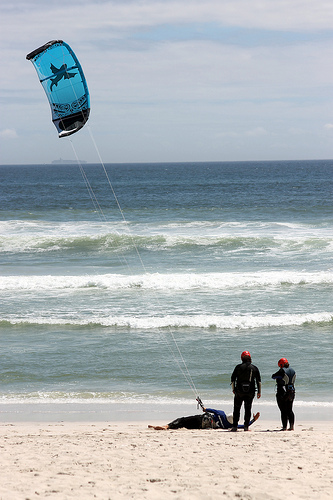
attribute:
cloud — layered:
[0, 1, 331, 48]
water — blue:
[1, 159, 331, 402]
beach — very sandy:
[0, 404, 332, 498]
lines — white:
[66, 126, 170, 306]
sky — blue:
[122, 30, 275, 129]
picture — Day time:
[35, 132, 223, 479]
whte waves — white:
[155, 213, 265, 272]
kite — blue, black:
[24, 36, 90, 139]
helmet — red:
[274, 356, 290, 366]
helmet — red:
[238, 348, 252, 359]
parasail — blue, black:
[24, 38, 90, 143]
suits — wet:
[231, 367, 288, 421]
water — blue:
[123, 164, 328, 212]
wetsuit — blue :
[269, 352, 304, 432]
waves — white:
[0, 267, 330, 303]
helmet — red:
[228, 343, 257, 362]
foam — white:
[7, 220, 325, 331]